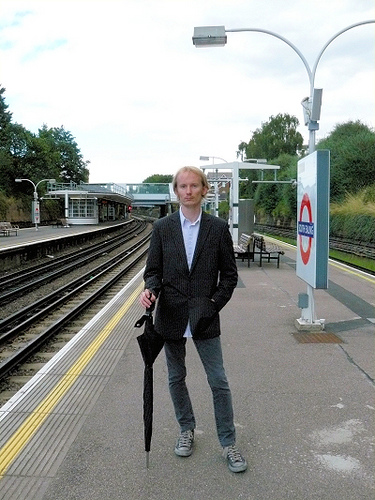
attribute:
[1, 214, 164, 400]
tracks — on ground, train tracks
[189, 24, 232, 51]
light — overhead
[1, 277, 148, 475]
line — yellow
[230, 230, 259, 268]
bench — on platform, existing, wooden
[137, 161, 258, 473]
man — standing, waiting, at station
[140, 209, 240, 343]
coat — black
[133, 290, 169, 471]
umbrella — black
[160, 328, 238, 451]
jeans — blue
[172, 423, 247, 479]
shoes — converse, with laces, grey, white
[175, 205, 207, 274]
shirt — white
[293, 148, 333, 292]
sign — advertisement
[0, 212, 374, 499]
platform — for boarding, public, train station, existing